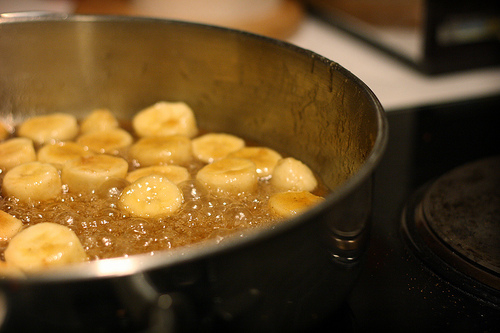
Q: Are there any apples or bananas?
A: Yes, there is a banana.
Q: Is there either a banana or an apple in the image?
A: Yes, there is a banana.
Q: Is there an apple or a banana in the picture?
A: Yes, there is a banana.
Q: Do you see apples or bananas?
A: Yes, there is a banana.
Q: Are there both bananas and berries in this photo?
A: No, there is a banana but no berries.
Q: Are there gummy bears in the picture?
A: No, there are no gummy bears.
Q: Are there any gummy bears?
A: No, there are no gummy bears.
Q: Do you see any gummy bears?
A: No, there are no gummy bears.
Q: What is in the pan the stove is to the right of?
A: The banana is in the pan.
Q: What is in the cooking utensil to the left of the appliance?
A: The banana is in the pan.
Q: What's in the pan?
A: The banana is in the pan.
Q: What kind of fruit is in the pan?
A: The fruit is a banana.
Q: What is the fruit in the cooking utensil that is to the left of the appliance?
A: The fruit is a banana.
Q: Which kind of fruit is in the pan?
A: The fruit is a banana.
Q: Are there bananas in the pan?
A: Yes, there is a banana in the pan.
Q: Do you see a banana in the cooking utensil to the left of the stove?
A: Yes, there is a banana in the pan.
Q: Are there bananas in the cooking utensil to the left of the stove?
A: Yes, there is a banana in the pan.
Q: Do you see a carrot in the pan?
A: No, there is a banana in the pan.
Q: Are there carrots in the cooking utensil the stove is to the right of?
A: No, there is a banana in the pan.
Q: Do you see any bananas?
A: Yes, there is a banana.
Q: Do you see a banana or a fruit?
A: Yes, there is a banana.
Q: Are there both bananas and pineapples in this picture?
A: No, there is a banana but no pineapples.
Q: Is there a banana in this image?
A: Yes, there is a banana.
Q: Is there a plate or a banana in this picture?
A: Yes, there is a banana.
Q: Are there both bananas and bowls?
A: No, there is a banana but no bowls.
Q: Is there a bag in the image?
A: No, there are no bags.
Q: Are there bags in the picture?
A: No, there are no bags.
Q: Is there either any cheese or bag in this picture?
A: No, there are no bags or cheese.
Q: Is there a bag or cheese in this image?
A: No, there are no bags or cheese.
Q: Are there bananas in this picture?
A: Yes, there is a banana.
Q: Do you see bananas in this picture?
A: Yes, there is a banana.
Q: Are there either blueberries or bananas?
A: Yes, there is a banana.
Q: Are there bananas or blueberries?
A: Yes, there is a banana.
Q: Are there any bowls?
A: No, there are no bowls.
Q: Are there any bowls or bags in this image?
A: No, there are no bowls or bags.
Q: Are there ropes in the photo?
A: No, there are no ropes.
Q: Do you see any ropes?
A: No, there are no ropes.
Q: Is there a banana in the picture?
A: Yes, there is a banana.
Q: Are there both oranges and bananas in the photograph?
A: No, there is a banana but no oranges.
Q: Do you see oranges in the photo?
A: No, there are no oranges.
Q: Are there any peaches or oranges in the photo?
A: No, there are no oranges or peaches.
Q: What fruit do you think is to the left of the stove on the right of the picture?
A: The fruit is a banana.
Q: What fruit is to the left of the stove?
A: The fruit is a banana.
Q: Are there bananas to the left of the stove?
A: Yes, there is a banana to the left of the stove.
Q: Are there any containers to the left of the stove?
A: No, there is a banana to the left of the stove.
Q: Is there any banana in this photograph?
A: Yes, there is a banana.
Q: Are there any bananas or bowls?
A: Yes, there is a banana.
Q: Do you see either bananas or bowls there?
A: Yes, there is a banana.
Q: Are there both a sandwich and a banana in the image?
A: No, there is a banana but no sandwiches.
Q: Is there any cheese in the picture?
A: No, there is no cheese.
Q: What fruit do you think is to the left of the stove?
A: The fruit is a banana.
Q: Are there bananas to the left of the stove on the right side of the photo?
A: Yes, there is a banana to the left of the stove.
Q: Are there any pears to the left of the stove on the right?
A: No, there is a banana to the left of the stove.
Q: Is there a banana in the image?
A: Yes, there is a banana.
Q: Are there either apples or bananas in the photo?
A: Yes, there is a banana.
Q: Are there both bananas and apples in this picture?
A: No, there is a banana but no apples.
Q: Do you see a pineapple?
A: No, there are no pineapples.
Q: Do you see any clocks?
A: No, there are no clocks.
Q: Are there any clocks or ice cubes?
A: No, there are no clocks or ice cubes.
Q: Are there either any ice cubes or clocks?
A: No, there are no clocks or ice cubes.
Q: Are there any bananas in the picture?
A: Yes, there is a banana.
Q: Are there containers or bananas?
A: Yes, there is a banana.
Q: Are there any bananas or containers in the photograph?
A: Yes, there is a banana.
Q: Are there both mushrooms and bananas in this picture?
A: No, there is a banana but no mushrooms.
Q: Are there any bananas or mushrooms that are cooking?
A: Yes, the banana is cooking.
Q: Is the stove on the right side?
A: Yes, the stove is on the right of the image.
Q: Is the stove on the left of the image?
A: No, the stove is on the right of the image.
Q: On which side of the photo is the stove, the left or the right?
A: The stove is on the right of the image.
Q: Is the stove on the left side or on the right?
A: The stove is on the right of the image.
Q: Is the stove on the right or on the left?
A: The stove is on the right of the image.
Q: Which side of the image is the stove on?
A: The stove is on the right of the image.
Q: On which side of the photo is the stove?
A: The stove is on the right of the image.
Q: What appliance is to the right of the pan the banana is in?
A: The appliance is a stove.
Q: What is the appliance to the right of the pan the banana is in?
A: The appliance is a stove.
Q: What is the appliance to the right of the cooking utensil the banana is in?
A: The appliance is a stove.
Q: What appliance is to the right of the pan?
A: The appliance is a stove.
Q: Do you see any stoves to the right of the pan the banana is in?
A: Yes, there is a stove to the right of the pan.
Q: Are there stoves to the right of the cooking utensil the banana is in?
A: Yes, there is a stove to the right of the pan.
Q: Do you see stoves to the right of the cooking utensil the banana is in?
A: Yes, there is a stove to the right of the pan.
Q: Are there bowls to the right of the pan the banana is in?
A: No, there is a stove to the right of the pan.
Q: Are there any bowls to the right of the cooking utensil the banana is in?
A: No, there is a stove to the right of the pan.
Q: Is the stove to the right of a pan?
A: Yes, the stove is to the right of a pan.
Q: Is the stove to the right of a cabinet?
A: No, the stove is to the right of a pan.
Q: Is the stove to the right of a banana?
A: Yes, the stove is to the right of a banana.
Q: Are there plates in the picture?
A: No, there are no plates.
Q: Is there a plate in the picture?
A: No, there are no plates.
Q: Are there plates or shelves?
A: No, there are no plates or shelves.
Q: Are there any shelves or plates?
A: No, there are no plates or shelves.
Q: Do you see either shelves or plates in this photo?
A: No, there are no plates or shelves.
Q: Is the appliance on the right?
A: Yes, the appliance is on the right of the image.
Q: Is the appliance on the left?
A: No, the appliance is on the right of the image.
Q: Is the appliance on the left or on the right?
A: The appliance is on the right of the image.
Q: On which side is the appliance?
A: The appliance is on the right of the image.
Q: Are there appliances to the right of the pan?
A: Yes, there is an appliance to the right of the pan.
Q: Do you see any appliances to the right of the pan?
A: Yes, there is an appliance to the right of the pan.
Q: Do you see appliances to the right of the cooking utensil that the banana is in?
A: Yes, there is an appliance to the right of the pan.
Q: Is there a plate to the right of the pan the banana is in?
A: No, there is an appliance to the right of the pan.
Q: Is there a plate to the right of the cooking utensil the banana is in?
A: No, there is an appliance to the right of the pan.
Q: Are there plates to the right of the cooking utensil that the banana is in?
A: No, there is an appliance to the right of the pan.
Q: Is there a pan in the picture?
A: Yes, there is a pan.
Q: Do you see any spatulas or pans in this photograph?
A: Yes, there is a pan.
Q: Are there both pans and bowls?
A: No, there is a pan but no bowls.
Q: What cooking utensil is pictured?
A: The cooking utensil is a pan.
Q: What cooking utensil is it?
A: The cooking utensil is a pan.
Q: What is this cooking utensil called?
A: This is a pan.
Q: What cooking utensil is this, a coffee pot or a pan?
A: This is a pan.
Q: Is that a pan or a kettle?
A: That is a pan.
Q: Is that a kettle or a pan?
A: That is a pan.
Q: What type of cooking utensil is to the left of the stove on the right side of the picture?
A: The cooking utensil is a pan.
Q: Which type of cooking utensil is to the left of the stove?
A: The cooking utensil is a pan.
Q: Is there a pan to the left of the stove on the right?
A: Yes, there is a pan to the left of the stove.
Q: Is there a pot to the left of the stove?
A: No, there is a pan to the left of the stove.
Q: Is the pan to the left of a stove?
A: Yes, the pan is to the left of a stove.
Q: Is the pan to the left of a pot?
A: No, the pan is to the left of a stove.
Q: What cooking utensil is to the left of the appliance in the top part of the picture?
A: The cooking utensil is a pan.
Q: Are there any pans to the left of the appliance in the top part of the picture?
A: Yes, there is a pan to the left of the appliance.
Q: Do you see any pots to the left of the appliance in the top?
A: No, there is a pan to the left of the appliance.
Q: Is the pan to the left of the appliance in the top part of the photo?
A: Yes, the pan is to the left of the appliance.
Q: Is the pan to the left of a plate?
A: No, the pan is to the left of the appliance.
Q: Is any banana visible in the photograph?
A: Yes, there is a banana.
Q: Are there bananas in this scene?
A: Yes, there is a banana.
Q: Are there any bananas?
A: Yes, there is a banana.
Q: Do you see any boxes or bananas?
A: Yes, there is a banana.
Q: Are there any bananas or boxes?
A: Yes, there is a banana.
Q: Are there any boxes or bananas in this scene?
A: Yes, there is a banana.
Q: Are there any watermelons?
A: No, there are no watermelons.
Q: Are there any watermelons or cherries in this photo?
A: No, there are no watermelons or cherries.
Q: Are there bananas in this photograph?
A: Yes, there is a banana.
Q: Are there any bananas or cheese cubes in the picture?
A: Yes, there is a banana.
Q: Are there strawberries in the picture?
A: No, there are no strawberries.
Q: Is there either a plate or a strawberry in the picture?
A: No, there are no strawberries or plates.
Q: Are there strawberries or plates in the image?
A: No, there are no strawberries or plates.